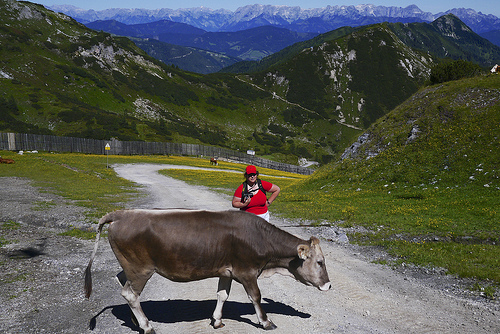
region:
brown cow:
[54, 192, 338, 303]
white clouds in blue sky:
[78, 6, 138, 47]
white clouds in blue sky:
[154, 9, 202, 46]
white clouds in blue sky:
[207, 6, 245, 33]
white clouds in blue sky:
[240, 15, 281, 46]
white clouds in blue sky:
[281, 8, 313, 38]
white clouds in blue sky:
[332, 12, 387, 47]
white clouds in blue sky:
[398, 16, 445, 43]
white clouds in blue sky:
[48, 6, 85, 40]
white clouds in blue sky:
[91, 9, 133, 34]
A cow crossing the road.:
[66, 187, 356, 322]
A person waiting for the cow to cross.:
[219, 160, 281, 252]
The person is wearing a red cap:
[236, 156, 265, 173]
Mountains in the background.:
[131, 11, 361, 70]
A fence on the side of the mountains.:
[23, 130, 248, 162]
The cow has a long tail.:
[72, 211, 107, 296]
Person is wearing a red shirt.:
[225, 183, 294, 223]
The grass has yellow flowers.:
[345, 177, 479, 238]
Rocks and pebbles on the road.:
[358, 254, 485, 323]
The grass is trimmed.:
[30, 150, 103, 197]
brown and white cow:
[78, 205, 332, 331]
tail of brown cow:
[71, 206, 103, 298]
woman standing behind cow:
[233, 159, 279, 220]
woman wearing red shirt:
[236, 160, 280, 215]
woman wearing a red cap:
[225, 158, 277, 215]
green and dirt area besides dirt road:
[0, 148, 120, 220]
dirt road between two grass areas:
[118, 154, 240, 211]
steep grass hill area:
[335, 64, 493, 209]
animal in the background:
[205, 155, 222, 170]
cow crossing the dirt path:
[70, 199, 330, 331]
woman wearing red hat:
[230, 151, 275, 201]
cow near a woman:
[80, 200, 340, 325]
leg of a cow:
[235, 265, 275, 327]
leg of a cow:
[200, 275, 235, 330]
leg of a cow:
[105, 272, 150, 327]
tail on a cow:
[80, 215, 110, 295]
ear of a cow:
[290, 236, 317, 261]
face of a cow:
[290, 237, 346, 294]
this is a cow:
[40, 179, 356, 332]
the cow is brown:
[83, 185, 328, 310]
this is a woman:
[225, 154, 291, 228]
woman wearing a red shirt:
[228, 178, 279, 218]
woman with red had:
[243, 161, 265, 183]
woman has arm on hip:
[260, 165, 291, 215]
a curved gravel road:
[88, 108, 421, 330]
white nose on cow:
[318, 274, 336, 296]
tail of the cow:
[49, 200, 117, 311]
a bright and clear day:
[14, 10, 491, 327]